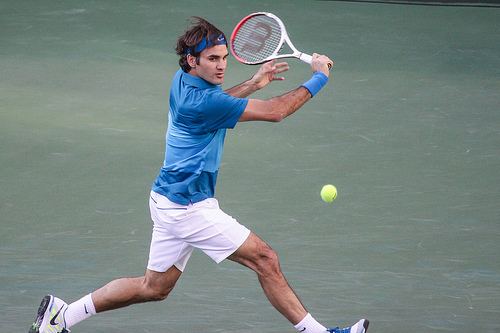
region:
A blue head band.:
[172, 35, 233, 52]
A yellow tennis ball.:
[320, 185, 338, 202]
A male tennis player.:
[26, 13, 371, 332]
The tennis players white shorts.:
[144, 198, 250, 270]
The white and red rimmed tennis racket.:
[231, 10, 331, 72]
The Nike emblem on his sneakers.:
[50, 302, 62, 332]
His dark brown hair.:
[178, 23, 222, 41]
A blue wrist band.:
[301, 73, 331, 98]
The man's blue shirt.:
[151, 69, 247, 206]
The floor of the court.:
[373, 57, 483, 189]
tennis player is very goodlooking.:
[25, 8, 373, 330]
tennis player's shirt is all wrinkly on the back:
[146, 81, 221, 205]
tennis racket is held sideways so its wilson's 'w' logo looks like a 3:
[235, 21, 276, 52]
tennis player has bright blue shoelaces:
[323, 321, 350, 329]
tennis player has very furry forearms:
[220, 76, 312, 122]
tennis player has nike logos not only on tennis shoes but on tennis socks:
[45, 290, 310, 330]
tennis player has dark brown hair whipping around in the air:
[170, 11, 231, 74]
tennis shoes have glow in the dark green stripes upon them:
[40, 305, 66, 331]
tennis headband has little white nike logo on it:
[213, 30, 228, 45]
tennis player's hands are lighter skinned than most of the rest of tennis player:
[250, 47, 341, 89]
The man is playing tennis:
[98, 17, 374, 315]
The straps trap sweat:
[145, 32, 370, 170]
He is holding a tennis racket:
[212, 22, 368, 142]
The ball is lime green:
[267, 157, 432, 259]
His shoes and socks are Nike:
[23, 295, 139, 330]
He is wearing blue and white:
[137, 75, 250, 287]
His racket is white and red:
[215, 15, 396, 115]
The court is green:
[68, 78, 430, 283]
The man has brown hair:
[145, 12, 320, 125]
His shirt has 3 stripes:
[117, 57, 333, 249]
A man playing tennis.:
[19, 9, 381, 331]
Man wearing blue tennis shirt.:
[146, 69, 254, 206]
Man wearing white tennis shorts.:
[131, 186, 266, 274]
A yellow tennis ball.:
[311, 181, 348, 202]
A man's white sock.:
[66, 292, 105, 331]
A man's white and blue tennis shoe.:
[15, 288, 76, 332]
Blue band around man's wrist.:
[299, 64, 339, 106]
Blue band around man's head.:
[176, 21, 229, 56]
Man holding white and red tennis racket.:
[225, 6, 347, 81]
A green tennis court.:
[373, 135, 498, 322]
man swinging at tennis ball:
[43, 9, 415, 331]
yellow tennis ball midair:
[317, 180, 337, 205]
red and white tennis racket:
[230, 5, 335, 76]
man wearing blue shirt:
[31, 12, 383, 331]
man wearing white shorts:
[39, 11, 387, 331]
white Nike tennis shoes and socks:
[23, 273, 118, 331]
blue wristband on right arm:
[290, 63, 347, 102]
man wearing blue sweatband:
[83, 12, 380, 332]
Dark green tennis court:
[15, 11, 484, 328]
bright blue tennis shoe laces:
[323, 316, 363, 331]